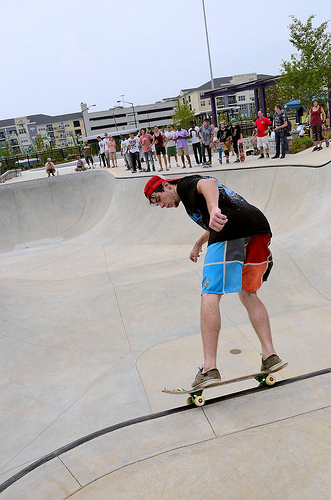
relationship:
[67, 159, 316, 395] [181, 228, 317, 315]
man in shorts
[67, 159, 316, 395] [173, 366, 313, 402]
man on skateboard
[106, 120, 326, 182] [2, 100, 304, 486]
people at skatepark